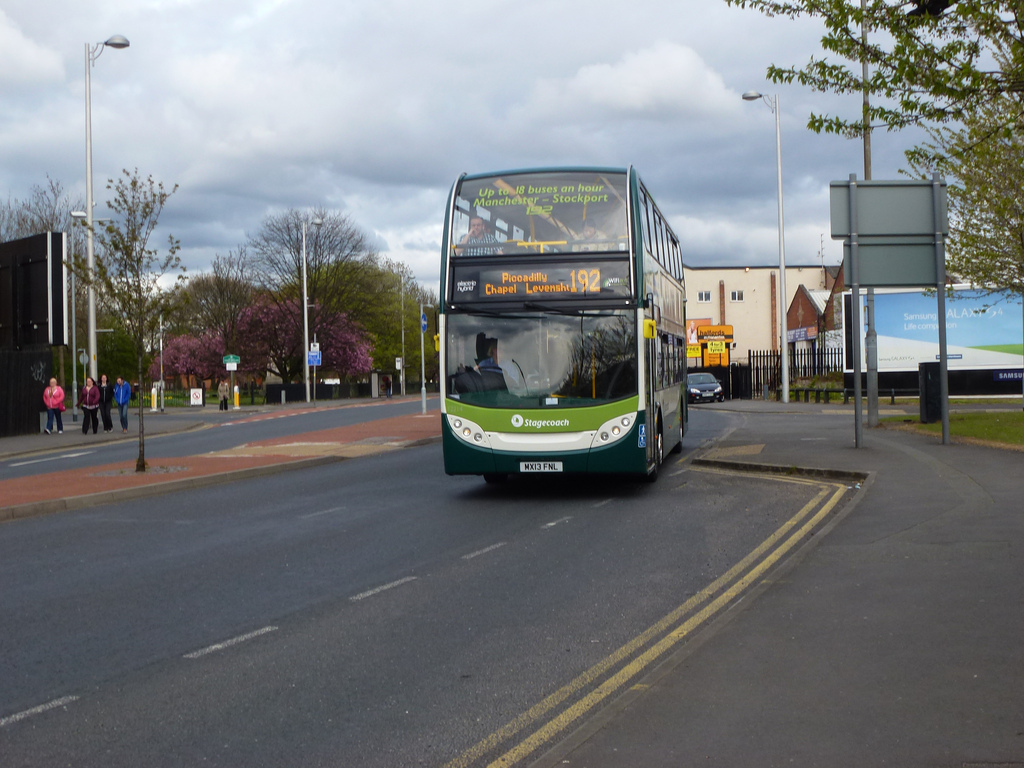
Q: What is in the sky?
A: Many clouds.